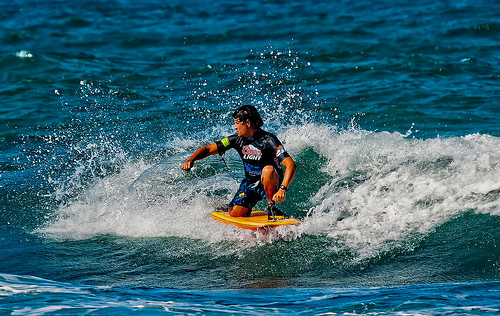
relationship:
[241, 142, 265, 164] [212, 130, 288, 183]
coors light logo printed on shirt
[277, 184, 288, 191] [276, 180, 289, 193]
watch on wrist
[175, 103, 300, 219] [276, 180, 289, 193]
surfer has wrist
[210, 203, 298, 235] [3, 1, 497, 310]
surfboard on sea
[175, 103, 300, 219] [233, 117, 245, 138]
surfer has face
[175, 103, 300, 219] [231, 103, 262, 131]
surfer has hair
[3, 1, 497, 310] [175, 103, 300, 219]
sea in front of surfer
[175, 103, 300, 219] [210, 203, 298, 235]
surfer kneeling on surfboard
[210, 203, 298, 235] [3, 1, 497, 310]
surfboard floating on sea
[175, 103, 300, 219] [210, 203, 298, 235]
surfer on surfboard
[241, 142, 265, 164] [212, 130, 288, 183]
coors light logo on shirt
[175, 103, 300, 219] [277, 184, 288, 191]
surfer has watch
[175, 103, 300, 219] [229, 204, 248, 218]
surfer has knee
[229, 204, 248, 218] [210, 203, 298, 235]
knee on surfboard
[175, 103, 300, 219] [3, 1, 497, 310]
surfer in sea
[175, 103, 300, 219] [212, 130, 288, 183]
surfer wearing shirt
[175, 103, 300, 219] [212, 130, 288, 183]
surfer has shirt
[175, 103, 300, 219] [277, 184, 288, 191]
surfer wearing watch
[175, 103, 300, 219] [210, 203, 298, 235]
surfer riding surfboard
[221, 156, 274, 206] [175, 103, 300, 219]
surfer leash attached to surfer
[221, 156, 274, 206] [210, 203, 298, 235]
surfer leash attached to surfboard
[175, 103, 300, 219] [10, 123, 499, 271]
surfer riding wave